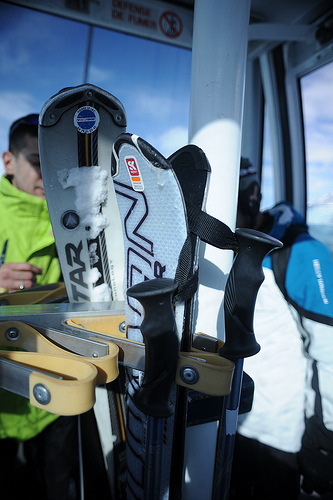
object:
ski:
[0, 300, 124, 328]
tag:
[73, 106, 100, 134]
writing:
[113, 178, 166, 500]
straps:
[0, 315, 127, 418]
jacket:
[0, 173, 84, 442]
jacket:
[268, 201, 333, 451]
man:
[235, 156, 333, 500]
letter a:
[69, 267, 89, 289]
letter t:
[70, 283, 90, 302]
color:
[0, 408, 115, 500]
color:
[181, 419, 220, 498]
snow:
[58, 164, 110, 303]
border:
[73, 105, 100, 134]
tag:
[124, 155, 145, 192]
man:
[0, 111, 111, 500]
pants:
[0, 408, 110, 500]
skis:
[35, 81, 185, 500]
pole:
[124, 275, 181, 500]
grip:
[126, 277, 180, 419]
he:
[0, 112, 117, 499]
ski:
[110, 131, 192, 500]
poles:
[126, 227, 283, 500]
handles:
[126, 226, 284, 419]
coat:
[238, 201, 319, 459]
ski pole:
[212, 225, 284, 500]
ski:
[37, 84, 126, 500]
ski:
[168, 142, 212, 500]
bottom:
[167, 143, 211, 232]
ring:
[19, 280, 24, 290]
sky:
[0, 0, 193, 174]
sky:
[297, 66, 333, 227]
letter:
[65, 239, 86, 267]